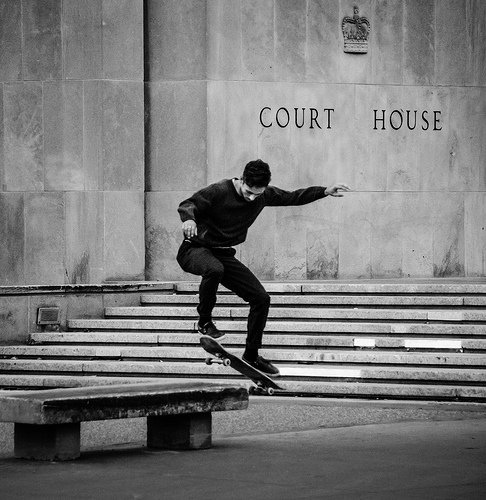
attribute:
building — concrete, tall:
[1, 1, 484, 343]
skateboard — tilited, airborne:
[199, 336, 287, 395]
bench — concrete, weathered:
[2, 377, 252, 464]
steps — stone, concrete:
[1, 280, 486, 403]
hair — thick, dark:
[245, 159, 272, 187]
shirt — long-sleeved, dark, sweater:
[179, 174, 326, 246]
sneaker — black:
[195, 321, 223, 339]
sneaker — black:
[242, 351, 280, 381]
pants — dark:
[176, 239, 271, 359]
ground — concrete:
[1, 394, 482, 500]